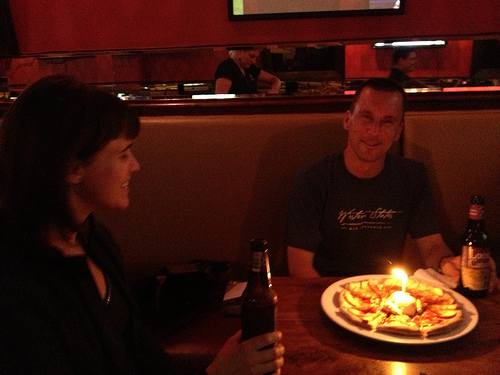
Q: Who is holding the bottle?
A: A man.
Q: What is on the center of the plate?
A: A candle.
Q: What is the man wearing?
A: A t-shirt.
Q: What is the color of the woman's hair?
A: Black.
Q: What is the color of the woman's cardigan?
A: Black.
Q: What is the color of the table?
A: Brown.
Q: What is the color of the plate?
A: White.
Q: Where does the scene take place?
A: In a restaurant.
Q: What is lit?
A: A candle.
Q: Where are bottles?
A: On the table.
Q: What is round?
A: Plate.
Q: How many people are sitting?
A: Two.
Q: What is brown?
A: Table.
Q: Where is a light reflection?
A: On the table.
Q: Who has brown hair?
A: The woman.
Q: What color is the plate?
A: White.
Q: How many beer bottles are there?
A: Two.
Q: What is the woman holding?
A: Beer.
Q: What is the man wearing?
A: T-shirt.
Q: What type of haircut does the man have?
A: Short.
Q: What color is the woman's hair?
A: Brown.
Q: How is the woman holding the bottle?
A: Her hand.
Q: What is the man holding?
A: Beer.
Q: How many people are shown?
A: 2.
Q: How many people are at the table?
A: Two.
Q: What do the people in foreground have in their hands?
A: Bottles.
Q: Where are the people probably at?
A: Bar.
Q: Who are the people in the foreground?
A: Man and woman.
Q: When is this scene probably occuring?
A: On birthday.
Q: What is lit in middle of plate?
A: Candle.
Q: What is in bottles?
A: Beer.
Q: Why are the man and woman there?
A: Celebrating.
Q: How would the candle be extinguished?
A: By blowing.